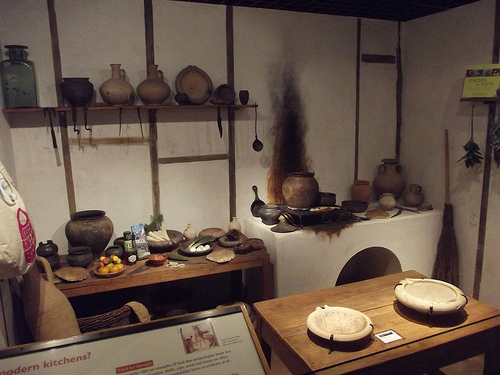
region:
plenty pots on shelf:
[78, 37, 292, 149]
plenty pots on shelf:
[27, 188, 229, 278]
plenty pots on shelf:
[150, 15, 264, 176]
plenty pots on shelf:
[64, 14, 211, 122]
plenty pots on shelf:
[35, 2, 236, 199]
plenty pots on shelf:
[100, 50, 221, 151]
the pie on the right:
[377, 265, 474, 326]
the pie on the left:
[296, 286, 378, 357]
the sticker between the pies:
[372, 323, 404, 357]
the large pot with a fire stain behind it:
[273, 164, 333, 208]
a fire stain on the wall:
[259, 53, 332, 216]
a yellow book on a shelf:
[452, 48, 496, 103]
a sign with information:
[4, 291, 252, 372]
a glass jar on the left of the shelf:
[0, 33, 46, 126]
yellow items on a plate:
[87, 251, 129, 280]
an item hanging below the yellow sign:
[452, 86, 486, 171]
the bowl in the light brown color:
[296, 293, 379, 354]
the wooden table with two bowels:
[253, 249, 495, 361]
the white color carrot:
[143, 211, 185, 250]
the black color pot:
[63, 204, 113, 256]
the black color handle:
[247, 100, 274, 162]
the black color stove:
[282, 194, 347, 227]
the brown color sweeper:
[429, 126, 463, 281]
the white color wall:
[297, 43, 354, 122]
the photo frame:
[459, 61, 498, 100]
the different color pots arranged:
[48, 34, 282, 149]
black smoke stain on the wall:
[267, 66, 319, 205]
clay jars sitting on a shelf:
[96, 62, 172, 106]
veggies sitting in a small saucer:
[94, 255, 125, 274]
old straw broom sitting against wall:
[434, 123, 467, 277]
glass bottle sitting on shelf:
[0, 45, 39, 105]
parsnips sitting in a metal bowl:
[145, 212, 182, 246]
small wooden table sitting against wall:
[12, 231, 277, 345]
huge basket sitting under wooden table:
[66, 297, 163, 327]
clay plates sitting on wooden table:
[308, 276, 469, 350]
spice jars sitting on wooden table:
[126, 228, 137, 248]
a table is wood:
[245, 265, 497, 374]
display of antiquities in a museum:
[3, 0, 495, 372]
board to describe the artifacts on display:
[0, 297, 277, 374]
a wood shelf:
[6, 100, 268, 141]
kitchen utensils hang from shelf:
[37, 110, 270, 167]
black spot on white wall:
[261, 64, 316, 173]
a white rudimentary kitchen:
[250, 200, 445, 280]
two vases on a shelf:
[96, 56, 174, 111]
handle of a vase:
[116, 66, 131, 79]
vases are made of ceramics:
[99, 52, 176, 113]